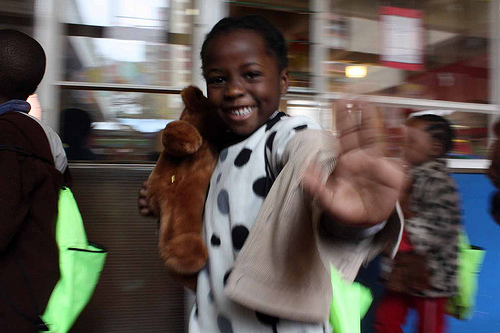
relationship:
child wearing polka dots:
[137, 13, 408, 331] [188, 110, 324, 331]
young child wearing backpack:
[365, 112, 476, 331] [454, 230, 484, 320]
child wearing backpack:
[181, 13, 415, 332] [321, 257, 373, 330]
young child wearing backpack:
[0, 24, 110, 331] [35, 167, 105, 331]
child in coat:
[181, 13, 415, 332] [380, 129, 488, 301]